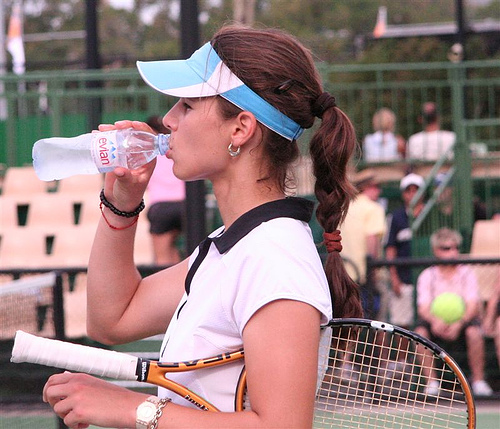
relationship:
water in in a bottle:
[32, 130, 120, 182] [31, 125, 169, 183]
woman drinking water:
[42, 21, 365, 427] [32, 130, 120, 182]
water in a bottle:
[32, 130, 120, 182] [31, 125, 169, 183]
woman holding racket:
[42, 21, 365, 427] [8, 316, 475, 428]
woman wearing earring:
[42, 21, 365, 427] [226, 142, 242, 157]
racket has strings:
[8, 316, 475, 428] [240, 327, 466, 428]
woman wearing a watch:
[42, 21, 365, 427] [133, 394, 159, 427]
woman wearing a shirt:
[42, 21, 365, 427] [154, 196, 333, 412]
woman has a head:
[42, 21, 365, 427] [162, 26, 321, 183]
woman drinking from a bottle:
[42, 21, 365, 427] [31, 125, 169, 183]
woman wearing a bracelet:
[42, 21, 365, 427] [150, 396, 172, 428]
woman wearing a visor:
[42, 21, 365, 427] [136, 39, 303, 142]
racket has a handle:
[8, 316, 475, 428] [10, 327, 140, 384]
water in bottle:
[32, 130, 120, 182] [31, 125, 169, 183]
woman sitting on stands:
[412, 228, 490, 399] [1, 153, 495, 396]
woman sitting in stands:
[412, 228, 490, 399] [1, 153, 495, 396]